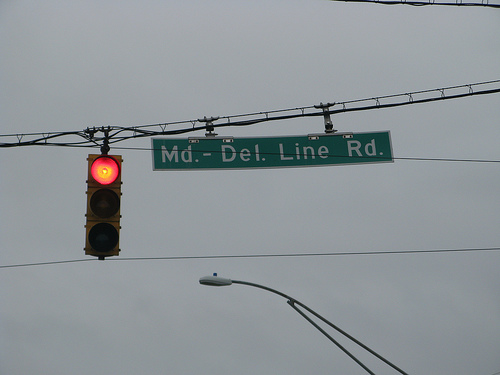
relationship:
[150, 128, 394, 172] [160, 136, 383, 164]
street sign with lettering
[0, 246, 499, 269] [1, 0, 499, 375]
power line stretching across sky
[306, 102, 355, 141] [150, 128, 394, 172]
bracket holding up street sign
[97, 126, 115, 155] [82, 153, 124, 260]
bracket holding up traffic signal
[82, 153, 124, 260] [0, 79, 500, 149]
traffic signal hanging from wire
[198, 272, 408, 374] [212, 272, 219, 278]
street lamp with light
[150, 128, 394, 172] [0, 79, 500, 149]
street sign hanging from wire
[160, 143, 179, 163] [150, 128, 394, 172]
letter on front of street sign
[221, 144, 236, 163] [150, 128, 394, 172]
letter on front of street sign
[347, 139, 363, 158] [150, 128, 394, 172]
letter on front of street sign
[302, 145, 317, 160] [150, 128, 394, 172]
letter on front of street sign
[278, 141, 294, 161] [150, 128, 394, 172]
letter on front of street sign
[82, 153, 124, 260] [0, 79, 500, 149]
traffic signal suspended by wire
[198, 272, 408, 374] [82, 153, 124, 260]
street lamp behind traffic signal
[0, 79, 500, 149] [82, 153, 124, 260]
cable stabilizes traffic signal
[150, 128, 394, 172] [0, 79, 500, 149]
street sign hangs from wire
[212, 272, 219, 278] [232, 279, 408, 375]
light at end of pole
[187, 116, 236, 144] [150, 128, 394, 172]
bracket hold up street sign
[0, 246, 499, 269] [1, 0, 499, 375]
power line runs across sky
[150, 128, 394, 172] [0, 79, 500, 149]
street sign hanging on wire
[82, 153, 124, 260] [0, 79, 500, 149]
traffic signal hanging on wire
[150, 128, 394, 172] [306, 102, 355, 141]
street sign has bracket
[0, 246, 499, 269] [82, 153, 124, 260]
power line below traffic signal